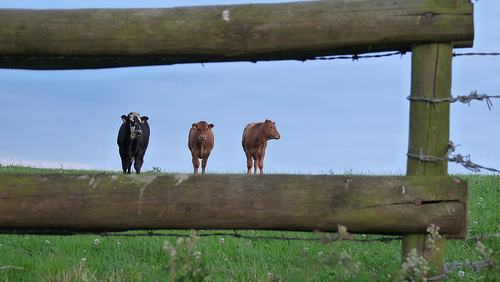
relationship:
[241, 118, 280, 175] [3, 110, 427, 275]
cow standing in field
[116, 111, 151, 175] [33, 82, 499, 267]
cow in field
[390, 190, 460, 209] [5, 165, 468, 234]
slit in post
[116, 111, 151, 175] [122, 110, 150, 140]
cow has head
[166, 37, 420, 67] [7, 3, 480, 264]
barbed wire on gate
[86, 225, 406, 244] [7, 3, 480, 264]
barbed wire on gate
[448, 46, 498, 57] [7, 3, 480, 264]
barbed wire on gate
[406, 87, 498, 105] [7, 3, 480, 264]
barbed wire on gate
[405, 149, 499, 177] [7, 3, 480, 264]
barbed wire on gate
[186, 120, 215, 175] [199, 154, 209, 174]
cow has leg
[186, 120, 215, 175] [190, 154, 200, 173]
cow has leg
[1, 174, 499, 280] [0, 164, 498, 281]
flower buds coming up from ground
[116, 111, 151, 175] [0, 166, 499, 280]
cow standing in grass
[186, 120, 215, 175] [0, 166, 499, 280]
cow standing in grass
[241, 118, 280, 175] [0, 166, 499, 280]
cow standing in grass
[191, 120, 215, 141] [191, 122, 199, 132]
head has ear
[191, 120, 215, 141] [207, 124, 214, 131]
head has ear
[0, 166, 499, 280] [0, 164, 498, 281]
grass on ground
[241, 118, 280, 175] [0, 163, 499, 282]
cow standing in field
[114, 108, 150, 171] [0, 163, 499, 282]
cow standing in field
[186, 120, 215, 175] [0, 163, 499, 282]
cow standing in field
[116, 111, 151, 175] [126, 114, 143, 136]
cow has face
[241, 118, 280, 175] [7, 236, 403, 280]
cow standing in pasture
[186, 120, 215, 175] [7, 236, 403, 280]
cow standing in pasture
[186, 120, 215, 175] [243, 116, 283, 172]
cow standing beside cow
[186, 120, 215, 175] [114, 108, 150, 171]
cow standing beside cow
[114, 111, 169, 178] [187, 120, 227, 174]
cow standing beside cow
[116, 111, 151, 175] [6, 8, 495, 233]
cow standing behind fence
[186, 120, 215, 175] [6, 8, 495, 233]
cow standing behind fence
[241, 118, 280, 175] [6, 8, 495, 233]
cow standing behind fence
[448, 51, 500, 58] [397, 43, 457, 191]
barbed wire tied to pole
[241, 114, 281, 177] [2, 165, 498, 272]
cow in field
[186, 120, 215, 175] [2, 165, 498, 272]
cow in field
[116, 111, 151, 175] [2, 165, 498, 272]
cow in field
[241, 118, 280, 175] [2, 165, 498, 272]
cow in field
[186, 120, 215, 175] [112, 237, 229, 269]
cow in field